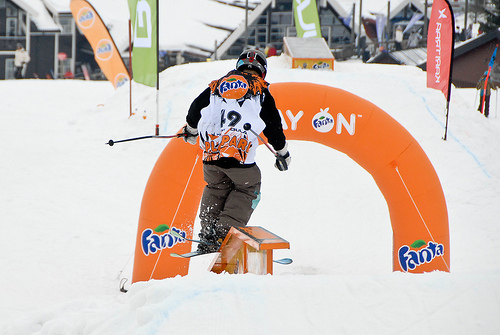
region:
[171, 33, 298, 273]
Person hold two ski poles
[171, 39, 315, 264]
Skier wears a helmet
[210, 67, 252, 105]
Person has a round advertisement on back that says "Fanta"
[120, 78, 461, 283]
Inflatable advertisement that says "Fanta"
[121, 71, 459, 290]
Inflatable advertisement is ornage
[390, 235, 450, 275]
Word "Fanta" is blue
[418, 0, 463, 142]
Red banner on a pole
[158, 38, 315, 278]
Skier is jumping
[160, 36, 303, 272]
Skier has a white vest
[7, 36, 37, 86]
Person walking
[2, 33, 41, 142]
a skier with a white jacket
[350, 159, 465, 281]
Orange and blue ad for soft drink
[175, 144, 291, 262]
brown pair of snow pants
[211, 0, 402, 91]
an A-framed building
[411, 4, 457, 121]
Red and white flag type sign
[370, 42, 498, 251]
Deep snowed slope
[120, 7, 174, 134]
Green and white sign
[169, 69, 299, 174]
black, white and orange parka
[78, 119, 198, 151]
a slightly bent ski pole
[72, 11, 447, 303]
snowboarder sliding down a ramp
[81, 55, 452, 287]
snowboarder participating in a competition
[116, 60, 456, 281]
inflated orange ring at end of ramp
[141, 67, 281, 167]
vest curled and hiding full number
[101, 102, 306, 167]
snowboarder holding poles pointing behind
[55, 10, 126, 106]
slanted vertical banner with advertisement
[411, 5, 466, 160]
red banner stuck in the snow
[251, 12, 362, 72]
slanted ramp in back of banner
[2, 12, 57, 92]
person standing in front of chalet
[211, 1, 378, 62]
slanting roof lines of chalet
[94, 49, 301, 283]
The person is skiing.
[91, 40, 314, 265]
The person is performing a skiing trick.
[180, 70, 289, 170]
The skier's jacket is black, white, and orange.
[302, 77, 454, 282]
The obstacle is orange.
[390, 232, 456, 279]
The obstacle is branded by Fanta.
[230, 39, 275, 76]
The skier wears a helmet.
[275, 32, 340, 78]
Another jump is in the background.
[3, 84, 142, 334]
The ground is covered with snow.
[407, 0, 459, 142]
A flag is in the snow.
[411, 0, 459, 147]
The flag is red.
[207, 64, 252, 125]
Orange and blue fanta sign.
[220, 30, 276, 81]
Gray and black helmet.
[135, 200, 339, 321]
Small ski slide.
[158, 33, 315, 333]
A person skiing in challenge.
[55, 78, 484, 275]
Orange fanta blow up tube.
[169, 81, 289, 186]
Black, white, orange, and blue ski jacket.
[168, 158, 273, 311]
Gray ski pants with blue patch on knee.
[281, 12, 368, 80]
Small ski ramp.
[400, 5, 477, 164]
Red and white flag in snow.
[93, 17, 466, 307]
Person skiing in a competition.